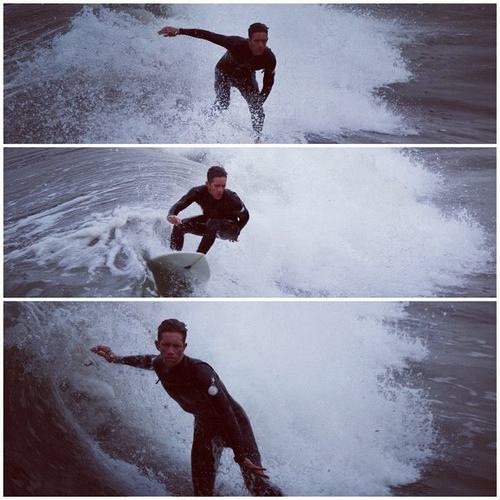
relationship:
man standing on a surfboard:
[89, 317, 284, 494] [144, 250, 215, 291]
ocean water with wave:
[4, 5, 495, 496] [52, 147, 226, 294]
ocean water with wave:
[4, 5, 495, 496] [6, 302, 181, 493]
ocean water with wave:
[4, 5, 495, 496] [7, 2, 196, 142]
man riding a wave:
[167, 165, 249, 255] [34, 147, 274, 307]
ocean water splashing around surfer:
[4, 5, 495, 496] [156, 22, 276, 141]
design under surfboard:
[179, 254, 201, 274] [147, 247, 209, 289]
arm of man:
[117, 354, 157, 370] [89, 317, 284, 494]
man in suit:
[89, 317, 284, 494] [124, 354, 273, 499]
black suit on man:
[120, 354, 286, 496] [89, 317, 284, 494]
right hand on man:
[86, 339, 109, 371] [89, 317, 284, 494]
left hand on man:
[235, 450, 271, 491] [89, 317, 284, 494]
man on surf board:
[167, 165, 249, 255] [144, 245, 210, 294]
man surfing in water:
[167, 165, 249, 255] [6, 145, 495, 295]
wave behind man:
[3, 301, 442, 495] [89, 317, 284, 494]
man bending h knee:
[167, 165, 249, 255] [203, 214, 220, 231]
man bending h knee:
[167, 165, 249, 255] [170, 217, 185, 232]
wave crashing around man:
[4, 10, 491, 140] [157, 21, 275, 145]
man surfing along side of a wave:
[167, 165, 249, 255] [6, 146, 491, 295]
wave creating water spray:
[4, 10, 491, 140] [60, 5, 363, 104]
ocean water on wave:
[4, 5, 495, 496] [364, 167, 446, 259]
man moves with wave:
[167, 165, 249, 255] [97, 144, 489, 296]